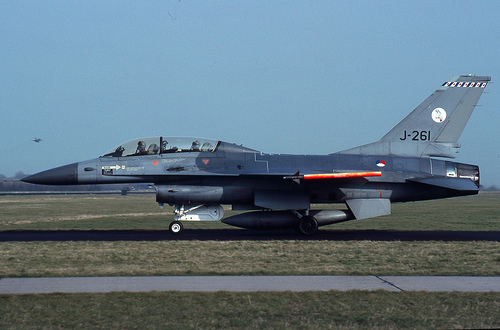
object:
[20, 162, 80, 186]
nose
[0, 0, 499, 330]
photo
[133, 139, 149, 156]
person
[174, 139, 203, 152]
person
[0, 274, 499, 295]
sidewalk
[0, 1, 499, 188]
sky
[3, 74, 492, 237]
jet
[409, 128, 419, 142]
number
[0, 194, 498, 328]
ground